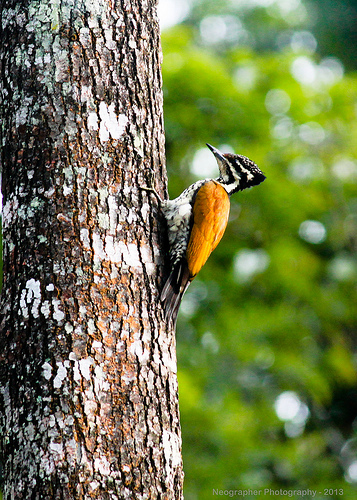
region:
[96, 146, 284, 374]
a bird si on atree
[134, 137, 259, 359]
the bird is walking through the ee tem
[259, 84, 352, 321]
the plants are green in color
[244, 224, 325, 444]
the plants are seen next to the tree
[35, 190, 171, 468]
the tree stem has some growimng orange plants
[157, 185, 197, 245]
the inside feathers are white in color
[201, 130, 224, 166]
the birds beak is long is size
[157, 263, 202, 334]
tail feathers are black in color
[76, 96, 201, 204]
the treestem has some white patches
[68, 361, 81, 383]
white spot on tree bark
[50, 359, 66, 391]
white spot on tree bark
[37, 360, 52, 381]
white spot on tree bark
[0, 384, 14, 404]
white spot on tree bark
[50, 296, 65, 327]
white spot on tree bark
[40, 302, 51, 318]
white spot on tree bark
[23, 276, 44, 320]
white spot on tree bark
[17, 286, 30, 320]
white spot on tree bark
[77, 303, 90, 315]
white spot on tree bark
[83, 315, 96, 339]
white spot on tree bark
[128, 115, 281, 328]
a bird on a tree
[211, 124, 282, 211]
the head of a bird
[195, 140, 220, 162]
the beak of a bird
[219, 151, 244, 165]
the eye of a bird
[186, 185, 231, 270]
the wing of a bird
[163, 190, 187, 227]
the feathers of a bird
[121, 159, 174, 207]
the feet of a bird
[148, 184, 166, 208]
the leg of a bird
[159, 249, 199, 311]
the tail feathers of a bird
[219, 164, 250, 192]
the stripes of a bird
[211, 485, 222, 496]
white print style letter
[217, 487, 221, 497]
white print style letter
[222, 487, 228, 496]
white print style letter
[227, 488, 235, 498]
white print style letter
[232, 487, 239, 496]
white print style letter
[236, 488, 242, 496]
white print style letter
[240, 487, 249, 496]
white print style letter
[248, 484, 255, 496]
white print style letter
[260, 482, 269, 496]
white print style letter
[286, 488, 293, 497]
white print style letter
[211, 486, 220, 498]
transparent print style letter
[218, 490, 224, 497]
transparent print style letter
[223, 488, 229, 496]
transparent print style letter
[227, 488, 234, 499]
transparent print style letter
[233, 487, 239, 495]
transparent print style letter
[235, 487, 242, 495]
transparent print style letter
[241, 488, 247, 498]
transparent print style letter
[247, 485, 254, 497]
transparent print style letter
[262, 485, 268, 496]
transparent print style letter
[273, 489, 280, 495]
transparent print style letter